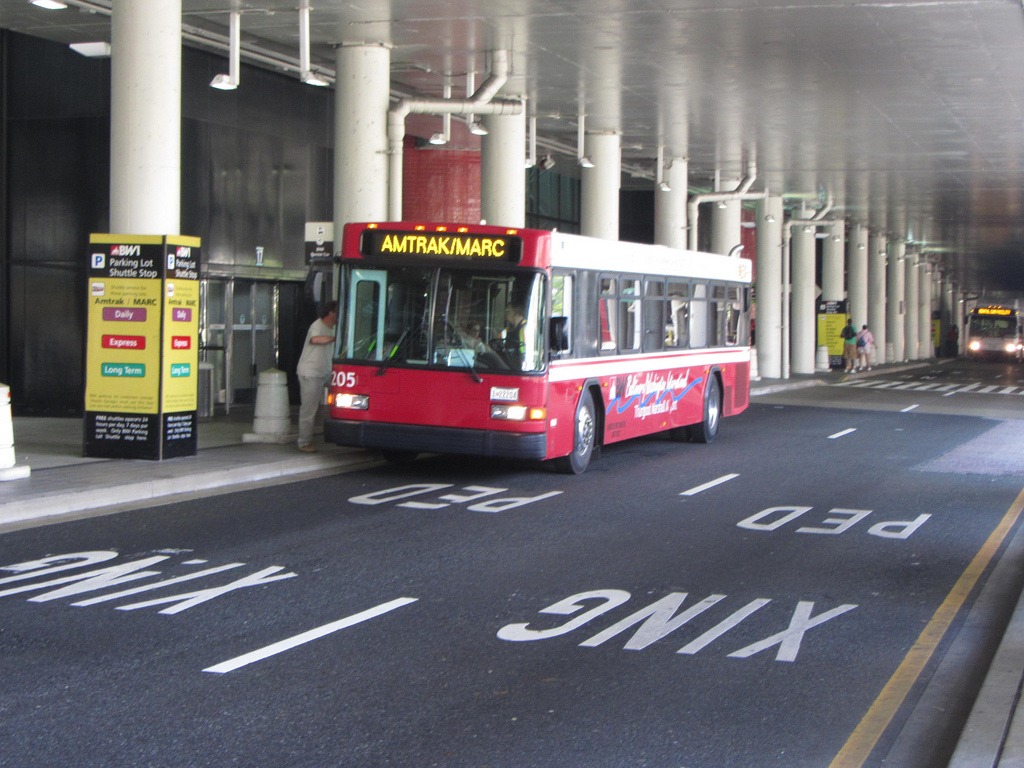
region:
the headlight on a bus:
[300, 371, 405, 433]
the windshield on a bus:
[337, 239, 568, 394]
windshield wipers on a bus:
[345, 279, 565, 412]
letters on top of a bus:
[340, 226, 550, 274]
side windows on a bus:
[530, 262, 724, 387]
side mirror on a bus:
[542, 302, 606, 366]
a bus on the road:
[297, 213, 857, 568]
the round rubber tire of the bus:
[567, 392, 599, 465]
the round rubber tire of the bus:
[699, 364, 726, 437]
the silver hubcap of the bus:
[577, 405, 594, 459]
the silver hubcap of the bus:
[706, 382, 719, 437]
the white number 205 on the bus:
[327, 368, 362, 387]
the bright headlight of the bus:
[332, 392, 372, 411]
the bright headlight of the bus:
[490, 401, 526, 418]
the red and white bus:
[317, 218, 757, 462]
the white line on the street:
[200, 584, 419, 682]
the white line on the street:
[672, 465, 739, 498]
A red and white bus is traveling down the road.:
[313, 206, 762, 457]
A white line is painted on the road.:
[198, 594, 427, 703]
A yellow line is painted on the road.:
[819, 554, 1004, 761]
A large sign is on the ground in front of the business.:
[72, 215, 215, 450]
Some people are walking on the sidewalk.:
[824, 309, 891, 370]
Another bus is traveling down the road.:
[966, 306, 1020, 377]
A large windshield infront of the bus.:
[341, 259, 551, 383]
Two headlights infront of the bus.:
[324, 386, 537, 435]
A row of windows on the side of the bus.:
[540, 271, 746, 371]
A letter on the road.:
[482, 564, 634, 654]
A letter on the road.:
[606, 560, 696, 678]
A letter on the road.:
[672, 569, 753, 667]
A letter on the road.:
[732, 567, 869, 675]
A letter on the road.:
[863, 485, 925, 547]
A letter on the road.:
[780, 488, 867, 549]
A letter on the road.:
[748, 491, 806, 531]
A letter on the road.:
[465, 472, 573, 530]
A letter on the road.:
[417, 476, 509, 527]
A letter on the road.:
[359, 472, 508, 520]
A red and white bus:
[339, 211, 757, 468]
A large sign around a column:
[83, 225, 200, 461]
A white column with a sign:
[108, 1, 194, 235]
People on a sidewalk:
[835, 320, 877, 379]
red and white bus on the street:
[322, 221, 756, 482]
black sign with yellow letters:
[354, 226, 523, 261]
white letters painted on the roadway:
[496, 581, 866, 668]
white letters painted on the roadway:
[731, 499, 935, 539]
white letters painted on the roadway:
[350, 480, 560, 528]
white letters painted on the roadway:
[0, 548, 305, 619]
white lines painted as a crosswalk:
[840, 369, 1021, 399]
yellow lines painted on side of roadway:
[831, 480, 1022, 763]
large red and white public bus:
[319, 223, 757, 474]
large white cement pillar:
[105, 3, 186, 242]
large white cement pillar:
[756, 189, 788, 386]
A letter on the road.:
[743, 579, 858, 668]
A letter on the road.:
[653, 566, 794, 684]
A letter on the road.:
[584, 577, 722, 679]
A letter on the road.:
[511, 573, 633, 656]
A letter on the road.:
[735, 491, 805, 543]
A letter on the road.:
[800, 497, 867, 542]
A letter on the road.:
[476, 488, 569, 520]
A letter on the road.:
[389, 479, 508, 524]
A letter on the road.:
[350, 473, 455, 503]